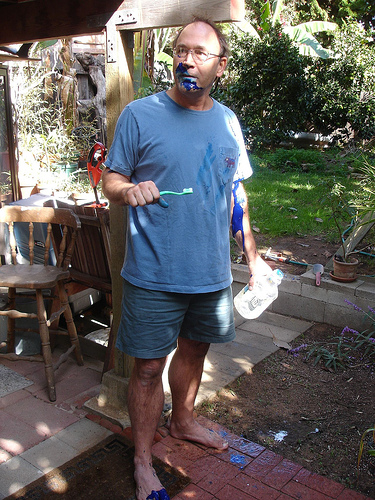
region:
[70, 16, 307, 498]
this is a man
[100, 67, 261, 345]
man wearing a blue shirt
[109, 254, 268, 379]
man wearing blue shorts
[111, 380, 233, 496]
man not wearing shoes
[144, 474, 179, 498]
paint on mans toes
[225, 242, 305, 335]
man holding a bottle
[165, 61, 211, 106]
man has paint on his face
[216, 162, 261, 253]
man has paint on his arm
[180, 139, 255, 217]
man has paint on his shirt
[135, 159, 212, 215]
man holding a toothbrush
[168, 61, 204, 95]
blue paint on man's face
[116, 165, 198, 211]
toothbrush in man's hand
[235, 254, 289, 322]
bottle in man's hand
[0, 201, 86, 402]
wood chair behind man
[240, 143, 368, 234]
green grass on ground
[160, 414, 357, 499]
red bricks on ground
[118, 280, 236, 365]
blue shorts on man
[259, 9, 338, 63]
big leaf on plant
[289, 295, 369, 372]
purple flower against concrete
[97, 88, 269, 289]
blue shirt on man's body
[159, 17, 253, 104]
head of a man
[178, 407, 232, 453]
foot of the man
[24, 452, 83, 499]
light hitting the ground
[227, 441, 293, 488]
red bricks on ground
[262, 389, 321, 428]
dirt on the ground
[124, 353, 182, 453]
leg of the man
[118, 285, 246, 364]
shorts on the man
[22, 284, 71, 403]
leg of the chair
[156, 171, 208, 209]
toothbrush in man's hand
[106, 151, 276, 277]
the man is covered in paint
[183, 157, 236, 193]
the paint is blue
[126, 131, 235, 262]
the man's shirt is blue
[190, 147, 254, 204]
the man's shirt is stained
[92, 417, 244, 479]
the man is barefoot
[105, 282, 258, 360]
the man has on shorts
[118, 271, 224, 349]
the shorts are gray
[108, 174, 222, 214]
this is a toothbrush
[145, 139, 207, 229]
the man is holding the toothbrush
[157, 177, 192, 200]
green toothbrush in hand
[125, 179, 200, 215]
hand holding green toothbrush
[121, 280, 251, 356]
grey shorts on man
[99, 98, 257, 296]
blue shirt on top of man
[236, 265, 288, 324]
water bottle in hand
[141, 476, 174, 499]
blue paint on foot of man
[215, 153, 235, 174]
small image on shirt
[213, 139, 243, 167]
small pocket on front of shirt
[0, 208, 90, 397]
brown seat on the ground